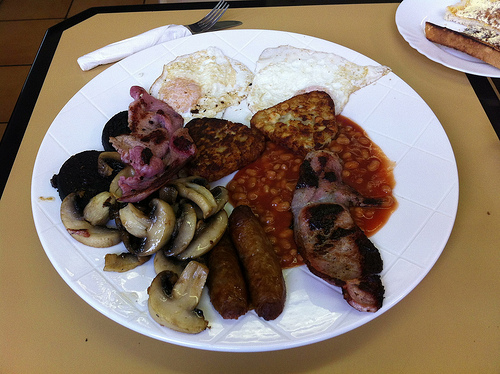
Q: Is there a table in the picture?
A: Yes, there is a table.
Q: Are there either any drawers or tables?
A: Yes, there is a table.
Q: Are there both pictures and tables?
A: No, there is a table but no pictures.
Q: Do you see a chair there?
A: No, there are no chairs.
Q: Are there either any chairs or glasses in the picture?
A: No, there are no chairs or glasses.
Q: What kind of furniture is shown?
A: The furniture is a table.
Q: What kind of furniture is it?
A: The piece of furniture is a table.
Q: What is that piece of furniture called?
A: This is a table.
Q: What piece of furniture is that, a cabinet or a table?
A: This is a table.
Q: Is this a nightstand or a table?
A: This is a table.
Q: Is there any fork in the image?
A: Yes, there is a fork.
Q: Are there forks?
A: Yes, there is a fork.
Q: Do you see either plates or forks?
A: Yes, there is a fork.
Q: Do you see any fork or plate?
A: Yes, there is a fork.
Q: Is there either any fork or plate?
A: Yes, there is a fork.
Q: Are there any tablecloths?
A: No, there are no tablecloths.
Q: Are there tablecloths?
A: No, there are no tablecloths.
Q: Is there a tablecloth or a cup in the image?
A: No, there are no tablecloths or cups.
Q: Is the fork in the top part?
A: Yes, the fork is in the top of the image.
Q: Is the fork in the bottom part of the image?
A: No, the fork is in the top of the image.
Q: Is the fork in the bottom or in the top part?
A: The fork is in the top of the image.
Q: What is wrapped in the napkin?
A: The fork is wrapped in the napkin.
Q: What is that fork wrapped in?
A: The fork is wrapped in a napkin.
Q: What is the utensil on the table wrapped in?
A: The fork is wrapped in a napkin.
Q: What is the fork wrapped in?
A: The fork is wrapped in a napkin.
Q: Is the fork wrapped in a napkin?
A: Yes, the fork is wrapped in a napkin.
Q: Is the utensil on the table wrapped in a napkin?
A: Yes, the fork is wrapped in a napkin.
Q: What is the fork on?
A: The fork is on the table.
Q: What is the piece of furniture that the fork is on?
A: The piece of furniture is a table.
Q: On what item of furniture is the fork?
A: The fork is on the table.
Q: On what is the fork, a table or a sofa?
A: The fork is on a table.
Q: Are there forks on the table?
A: Yes, there is a fork on the table.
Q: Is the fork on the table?
A: Yes, the fork is on the table.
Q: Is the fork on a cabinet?
A: No, the fork is on the table.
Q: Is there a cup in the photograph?
A: No, there are no cups.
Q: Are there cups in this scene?
A: No, there are no cups.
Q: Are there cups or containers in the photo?
A: No, there are no cups or containers.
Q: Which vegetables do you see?
A: The vegetables are beans.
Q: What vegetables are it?
A: The vegetables are beans.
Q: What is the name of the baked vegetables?
A: The vegetables are beans.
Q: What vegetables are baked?
A: The vegetables are beans.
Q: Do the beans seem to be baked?
A: Yes, the beans are baked.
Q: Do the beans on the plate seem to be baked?
A: Yes, the beans are baked.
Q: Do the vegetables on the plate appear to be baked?
A: Yes, the beans are baked.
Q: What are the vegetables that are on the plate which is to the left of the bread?
A: The vegetables are beans.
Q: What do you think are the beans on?
A: The beans are on the plate.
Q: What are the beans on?
A: The beans are on the plate.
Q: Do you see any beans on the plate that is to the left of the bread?
A: Yes, there are beans on the plate.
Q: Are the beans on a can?
A: No, the beans are on the plate.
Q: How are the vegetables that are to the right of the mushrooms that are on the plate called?
A: The vegetables are beans.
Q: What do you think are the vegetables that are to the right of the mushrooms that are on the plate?
A: The vegetables are beans.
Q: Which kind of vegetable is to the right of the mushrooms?
A: The vegetables are beans.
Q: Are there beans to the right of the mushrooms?
A: Yes, there are beans to the right of the mushrooms.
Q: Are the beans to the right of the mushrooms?
A: Yes, the beans are to the right of the mushrooms.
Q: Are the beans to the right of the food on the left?
A: Yes, the beans are to the right of the mushrooms.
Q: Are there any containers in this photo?
A: No, there are no containers.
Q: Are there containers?
A: No, there are no containers.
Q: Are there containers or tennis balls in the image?
A: No, there are no containers or tennis balls.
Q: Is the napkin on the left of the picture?
A: Yes, the napkin is on the left of the image.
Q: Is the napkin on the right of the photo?
A: No, the napkin is on the left of the image.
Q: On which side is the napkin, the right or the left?
A: The napkin is on the left of the image.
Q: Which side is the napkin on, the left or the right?
A: The napkin is on the left of the image.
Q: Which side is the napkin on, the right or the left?
A: The napkin is on the left of the image.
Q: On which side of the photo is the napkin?
A: The napkin is on the left of the image.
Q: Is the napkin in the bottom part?
A: No, the napkin is in the top of the image.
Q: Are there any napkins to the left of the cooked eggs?
A: Yes, there is a napkin to the left of the eggs.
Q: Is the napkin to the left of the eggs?
A: Yes, the napkin is to the left of the eggs.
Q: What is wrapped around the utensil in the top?
A: The napkin is wrapped around the fork.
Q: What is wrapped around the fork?
A: The napkin is wrapped around the fork.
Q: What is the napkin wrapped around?
A: The napkin is wrapped around the fork.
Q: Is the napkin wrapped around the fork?
A: Yes, the napkin is wrapped around the fork.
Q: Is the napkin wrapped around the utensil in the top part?
A: Yes, the napkin is wrapped around the fork.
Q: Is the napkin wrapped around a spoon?
A: No, the napkin is wrapped around the fork.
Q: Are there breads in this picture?
A: Yes, there is a bread.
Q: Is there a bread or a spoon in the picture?
A: Yes, there is a bread.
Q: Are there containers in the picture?
A: No, there are no containers.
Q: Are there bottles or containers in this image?
A: No, there are no containers or bottles.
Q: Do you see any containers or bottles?
A: No, there are no containers or bottles.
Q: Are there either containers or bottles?
A: No, there are no containers or bottles.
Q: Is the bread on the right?
A: Yes, the bread is on the right of the image.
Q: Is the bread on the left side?
A: No, the bread is on the right of the image.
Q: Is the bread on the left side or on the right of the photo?
A: The bread is on the right of the image.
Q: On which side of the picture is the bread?
A: The bread is on the right of the image.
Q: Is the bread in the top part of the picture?
A: Yes, the bread is in the top of the image.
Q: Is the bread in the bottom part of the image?
A: No, the bread is in the top of the image.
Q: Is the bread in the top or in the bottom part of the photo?
A: The bread is in the top of the image.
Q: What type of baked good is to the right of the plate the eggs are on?
A: The food is a bread.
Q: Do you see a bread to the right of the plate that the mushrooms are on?
A: Yes, there is a bread to the right of the plate.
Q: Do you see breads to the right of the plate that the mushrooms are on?
A: Yes, there is a bread to the right of the plate.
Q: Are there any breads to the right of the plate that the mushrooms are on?
A: Yes, there is a bread to the right of the plate.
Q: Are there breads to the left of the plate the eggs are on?
A: No, the bread is to the right of the plate.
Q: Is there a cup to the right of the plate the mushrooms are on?
A: No, there is a bread to the right of the plate.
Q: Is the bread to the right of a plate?
A: Yes, the bread is to the right of a plate.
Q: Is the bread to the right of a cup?
A: No, the bread is to the right of a plate.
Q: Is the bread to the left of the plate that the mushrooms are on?
A: No, the bread is to the right of the plate.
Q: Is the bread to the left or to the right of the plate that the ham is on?
A: The bread is to the right of the plate.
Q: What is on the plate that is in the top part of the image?
A: The bread is on the plate.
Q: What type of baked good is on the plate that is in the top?
A: The food is a bread.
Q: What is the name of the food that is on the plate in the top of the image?
A: The food is a bread.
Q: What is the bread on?
A: The bread is on the plate.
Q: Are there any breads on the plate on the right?
A: Yes, there is a bread on the plate.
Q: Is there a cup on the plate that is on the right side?
A: No, there is a bread on the plate.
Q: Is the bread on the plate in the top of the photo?
A: Yes, the bread is on the plate.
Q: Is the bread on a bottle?
A: No, the bread is on the plate.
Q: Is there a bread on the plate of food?
A: Yes, there is a bread on the plate.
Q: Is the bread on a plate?
A: Yes, the bread is on a plate.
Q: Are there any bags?
A: No, there are no bags.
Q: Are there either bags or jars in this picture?
A: No, there are no bags or jars.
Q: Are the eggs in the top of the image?
A: Yes, the eggs are in the top of the image.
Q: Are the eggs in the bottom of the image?
A: No, the eggs are in the top of the image.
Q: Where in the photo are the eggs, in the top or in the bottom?
A: The eggs are in the top of the image.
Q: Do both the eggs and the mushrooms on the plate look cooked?
A: Yes, both the eggs and the mushrooms are cooked.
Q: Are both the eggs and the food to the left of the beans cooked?
A: Yes, both the eggs and the mushrooms are cooked.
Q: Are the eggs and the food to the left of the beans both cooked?
A: Yes, both the eggs and the mushrooms are cooked.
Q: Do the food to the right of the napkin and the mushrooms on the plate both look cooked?
A: Yes, both the eggs and the mushrooms are cooked.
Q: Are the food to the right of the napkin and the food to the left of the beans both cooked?
A: Yes, both the eggs and the mushrooms are cooked.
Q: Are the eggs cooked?
A: Yes, the eggs are cooked.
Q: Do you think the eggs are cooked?
A: Yes, the eggs are cooked.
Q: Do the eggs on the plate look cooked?
A: Yes, the eggs are cooked.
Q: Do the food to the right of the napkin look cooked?
A: Yes, the eggs are cooked.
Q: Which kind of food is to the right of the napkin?
A: The food is eggs.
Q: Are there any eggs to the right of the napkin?
A: Yes, there are eggs to the right of the napkin.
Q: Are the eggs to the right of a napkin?
A: Yes, the eggs are to the right of a napkin.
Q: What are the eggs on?
A: The eggs are on the plate.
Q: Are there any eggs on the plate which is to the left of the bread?
A: Yes, there are eggs on the plate.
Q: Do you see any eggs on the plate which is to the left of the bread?
A: Yes, there are eggs on the plate.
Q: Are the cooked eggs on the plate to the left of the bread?
A: Yes, the eggs are on the plate.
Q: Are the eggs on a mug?
A: No, the eggs are on the plate.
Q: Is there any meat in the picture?
A: Yes, there is meat.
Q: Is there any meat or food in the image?
A: Yes, there is meat.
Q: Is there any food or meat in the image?
A: Yes, there is meat.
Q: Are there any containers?
A: No, there are no containers.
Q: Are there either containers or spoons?
A: No, there are no containers or spoons.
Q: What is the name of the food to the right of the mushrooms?
A: The food is meat.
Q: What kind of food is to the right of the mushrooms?
A: The food is meat.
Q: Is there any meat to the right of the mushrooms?
A: Yes, there is meat to the right of the mushrooms.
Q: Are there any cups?
A: No, there are no cups.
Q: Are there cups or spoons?
A: No, there are no cups or spoons.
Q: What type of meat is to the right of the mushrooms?
A: The meat is ham.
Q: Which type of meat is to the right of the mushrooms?
A: The meat is ham.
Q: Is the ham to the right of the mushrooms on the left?
A: Yes, the ham is to the right of the mushrooms.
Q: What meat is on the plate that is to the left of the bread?
A: The meat is ham.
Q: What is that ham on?
A: The ham is on the plate.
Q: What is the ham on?
A: The ham is on the plate.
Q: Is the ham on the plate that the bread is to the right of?
A: Yes, the ham is on the plate.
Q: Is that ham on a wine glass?
A: No, the ham is on the plate.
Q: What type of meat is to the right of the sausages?
A: The meat is ham.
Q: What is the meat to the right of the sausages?
A: The meat is ham.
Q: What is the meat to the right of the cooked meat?
A: The meat is ham.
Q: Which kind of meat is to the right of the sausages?
A: The meat is ham.